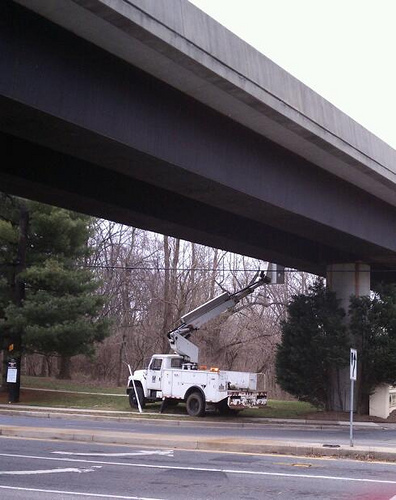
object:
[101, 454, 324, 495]
line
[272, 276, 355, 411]
tree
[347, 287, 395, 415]
trees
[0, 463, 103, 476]
arrow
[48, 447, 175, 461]
arrow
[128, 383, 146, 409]
front tire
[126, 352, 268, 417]
truck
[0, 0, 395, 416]
overpass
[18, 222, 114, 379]
gold handle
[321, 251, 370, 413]
pillar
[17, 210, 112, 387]
tree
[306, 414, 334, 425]
sidewalk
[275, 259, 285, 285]
cage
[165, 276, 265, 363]
lift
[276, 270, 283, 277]
lights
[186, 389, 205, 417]
tire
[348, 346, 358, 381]
sign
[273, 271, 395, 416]
bush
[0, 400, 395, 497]
road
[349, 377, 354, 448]
post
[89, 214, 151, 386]
trees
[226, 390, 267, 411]
rust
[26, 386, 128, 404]
grass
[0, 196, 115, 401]
tree